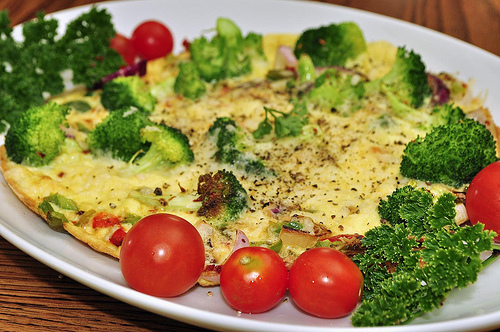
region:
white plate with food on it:
[0, 3, 487, 330]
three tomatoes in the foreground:
[118, 208, 380, 325]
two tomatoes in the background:
[70, 8, 169, 70]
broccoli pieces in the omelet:
[12, 39, 432, 236]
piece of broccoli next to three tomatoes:
[355, 196, 485, 324]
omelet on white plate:
[1, 31, 497, 275]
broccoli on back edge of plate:
[1, 7, 116, 99]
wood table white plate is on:
[1, 5, 488, 325]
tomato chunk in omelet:
[91, 208, 122, 245]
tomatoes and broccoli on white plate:
[5, 1, 497, 308]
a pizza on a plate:
[0, 63, 482, 255]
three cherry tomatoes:
[105, 215, 372, 310]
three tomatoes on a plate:
[108, 204, 370, 315]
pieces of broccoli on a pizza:
[33, 27, 390, 188]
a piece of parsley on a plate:
[360, 188, 485, 297]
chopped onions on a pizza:
[208, 207, 343, 259]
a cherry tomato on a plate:
[116, 204, 214, 316]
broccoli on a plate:
[14, 97, 214, 184]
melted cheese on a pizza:
[80, 153, 181, 203]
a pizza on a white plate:
[63, 36, 499, 328]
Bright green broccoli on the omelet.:
[5, 95, 67, 169]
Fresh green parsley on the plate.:
[4, 5, 123, 116]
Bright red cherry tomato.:
[117, 208, 204, 300]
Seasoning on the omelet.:
[280, 125, 372, 202]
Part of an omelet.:
[24, 164, 171, 247]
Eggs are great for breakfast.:
[134, 80, 353, 217]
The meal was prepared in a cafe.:
[57, 50, 451, 206]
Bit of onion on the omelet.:
[270, 225, 321, 250]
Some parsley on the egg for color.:
[250, 90, 311, 140]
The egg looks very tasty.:
[108, 41, 428, 203]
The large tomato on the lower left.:
[115, 215, 205, 302]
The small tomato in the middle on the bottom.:
[220, 240, 285, 315]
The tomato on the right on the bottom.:
[285, 241, 365, 312]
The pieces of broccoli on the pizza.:
[6, 26, 462, 233]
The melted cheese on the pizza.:
[55, 60, 427, 244]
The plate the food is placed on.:
[19, 12, 499, 324]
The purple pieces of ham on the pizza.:
[250, 44, 452, 119]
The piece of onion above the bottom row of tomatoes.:
[270, 207, 320, 246]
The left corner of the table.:
[1, 252, 128, 330]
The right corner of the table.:
[385, 0, 499, 50]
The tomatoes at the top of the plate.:
[105, 20, 180, 66]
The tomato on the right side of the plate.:
[463, 150, 498, 240]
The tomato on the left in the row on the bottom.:
[111, 213, 207, 299]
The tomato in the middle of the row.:
[215, 243, 283, 312]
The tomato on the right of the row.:
[295, 247, 362, 315]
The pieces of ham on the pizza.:
[61, 61, 376, 268]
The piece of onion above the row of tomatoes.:
[268, 203, 327, 244]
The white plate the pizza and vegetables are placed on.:
[7, 2, 498, 318]